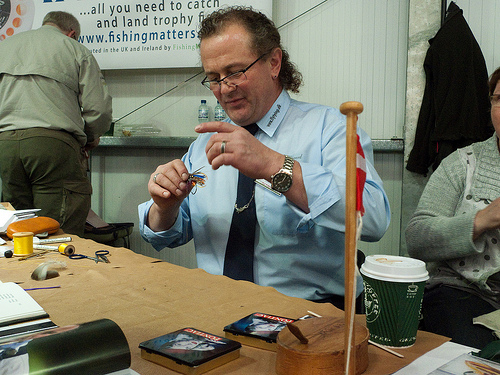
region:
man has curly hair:
[206, 13, 293, 82]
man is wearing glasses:
[191, 56, 297, 112]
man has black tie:
[233, 118, 314, 298]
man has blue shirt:
[263, 119, 313, 295]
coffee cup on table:
[373, 218, 434, 372]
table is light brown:
[44, 301, 237, 352]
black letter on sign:
[89, 5, 97, 17]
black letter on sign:
[95, 0, 102, 14]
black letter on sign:
[100, 1, 106, 16]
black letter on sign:
[108, 3, 115, 16]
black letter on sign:
[115, 4, 123, 13]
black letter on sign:
[122, 3, 132, 14]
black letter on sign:
[95, 18, 103, 29]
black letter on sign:
[100, 18, 112, 28]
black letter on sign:
[124, 16, 133, 28]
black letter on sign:
[163, 14, 170, 26]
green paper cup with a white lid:
[359, 253, 429, 345]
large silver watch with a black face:
[269, 155, 293, 195]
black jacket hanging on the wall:
[404, 1, 493, 174]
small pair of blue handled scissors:
[68, 250, 108, 264]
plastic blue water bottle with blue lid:
[197, 99, 208, 124]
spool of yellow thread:
[13, 232, 33, 254]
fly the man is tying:
[186, 166, 206, 193]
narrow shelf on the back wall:
[90, 135, 404, 151]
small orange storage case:
[7, 215, 59, 237]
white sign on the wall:
[0, 0, 271, 66]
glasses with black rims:
[199, 50, 271, 92]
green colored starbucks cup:
[359, 253, 430, 347]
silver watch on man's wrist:
[266, 154, 294, 194]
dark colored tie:
[223, 125, 258, 280]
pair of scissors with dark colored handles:
[68, 250, 114, 262]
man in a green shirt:
[3, 9, 113, 236]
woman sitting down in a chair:
[405, 67, 498, 349]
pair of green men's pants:
[1, 128, 88, 233]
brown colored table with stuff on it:
[1, 218, 498, 372]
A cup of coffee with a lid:
[356, 251, 426, 346]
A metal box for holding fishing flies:
[135, 325, 240, 370]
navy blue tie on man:
[220, 125, 255, 285]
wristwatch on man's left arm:
[269, 155, 299, 195]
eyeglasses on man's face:
[200, 44, 287, 91]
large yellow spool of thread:
[10, 233, 35, 259]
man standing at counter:
[2, 8, 113, 236]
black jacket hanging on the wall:
[403, 0, 498, 176]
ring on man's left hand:
[217, 140, 226, 154]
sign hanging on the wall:
[1, 0, 272, 73]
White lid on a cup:
[355, 250, 430, 285]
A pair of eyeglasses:
[196, 45, 276, 95]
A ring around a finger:
[215, 135, 230, 157]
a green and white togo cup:
[355, 244, 438, 360]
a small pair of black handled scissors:
[71, 245, 113, 267]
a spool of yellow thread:
[54, 240, 77, 260]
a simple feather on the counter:
[25, 251, 72, 281]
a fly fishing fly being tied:
[183, 159, 209, 199]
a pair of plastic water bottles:
[193, 96, 230, 135]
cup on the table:
[370, 259, 420, 341]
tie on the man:
[197, 218, 268, 265]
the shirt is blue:
[184, 219, 218, 249]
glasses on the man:
[208, 71, 239, 88]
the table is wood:
[127, 300, 152, 310]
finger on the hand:
[197, 117, 234, 131]